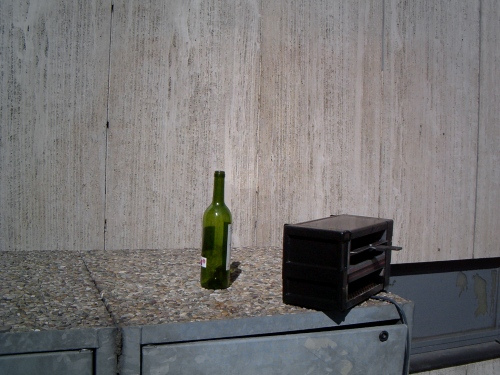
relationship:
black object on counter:
[270, 206, 404, 321] [4, 238, 421, 374]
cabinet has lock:
[5, 294, 421, 374] [373, 326, 397, 352]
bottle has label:
[193, 165, 238, 293] [215, 217, 237, 271]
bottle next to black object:
[193, 165, 238, 293] [270, 206, 404, 321]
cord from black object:
[373, 293, 426, 374] [270, 206, 404, 321]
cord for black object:
[373, 293, 426, 374] [270, 206, 404, 321]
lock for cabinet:
[373, 326, 397, 352] [5, 294, 421, 374]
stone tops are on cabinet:
[7, 241, 413, 336] [5, 294, 421, 374]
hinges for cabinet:
[77, 334, 157, 374] [5, 294, 421, 374]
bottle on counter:
[193, 165, 238, 293] [4, 238, 421, 374]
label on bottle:
[215, 217, 237, 271] [193, 165, 238, 293]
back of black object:
[278, 223, 350, 315] [270, 206, 404, 321]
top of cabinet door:
[127, 299, 408, 345] [142, 319, 408, 374]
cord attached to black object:
[373, 293, 426, 374] [270, 206, 404, 321]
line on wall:
[96, 3, 118, 258] [3, 1, 500, 256]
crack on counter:
[73, 248, 130, 336] [4, 238, 421, 374]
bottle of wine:
[193, 165, 238, 293] [201, 237, 227, 287]